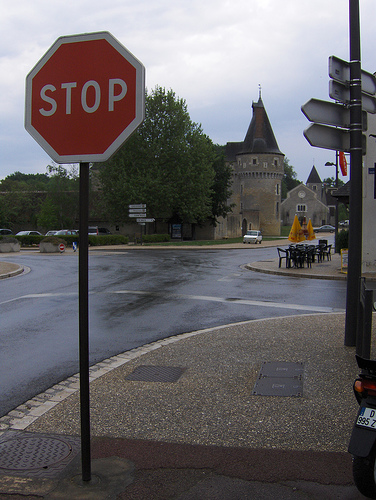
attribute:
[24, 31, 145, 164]
sign — red, directive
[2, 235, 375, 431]
street — asphalt, wet, intersection, shiny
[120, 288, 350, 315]
line — white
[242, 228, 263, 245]
car — white, parked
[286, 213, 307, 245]
umbrella — yellow, closed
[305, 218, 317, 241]
umbrella — yellow, closed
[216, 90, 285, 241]
building — brick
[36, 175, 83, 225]
tree — green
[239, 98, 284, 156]
roof — coneical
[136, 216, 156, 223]
sign — long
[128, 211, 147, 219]
sign — long